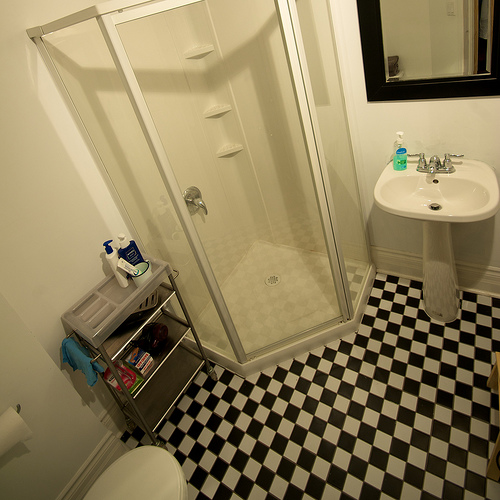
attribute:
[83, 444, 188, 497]
toilet — white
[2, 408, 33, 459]
toilet paper — white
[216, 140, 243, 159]
shelf — small 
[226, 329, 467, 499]
floor — checkered 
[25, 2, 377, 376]
shower — glass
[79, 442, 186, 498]
seat — white 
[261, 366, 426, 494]
flooring — black, white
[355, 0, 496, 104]
frames — black